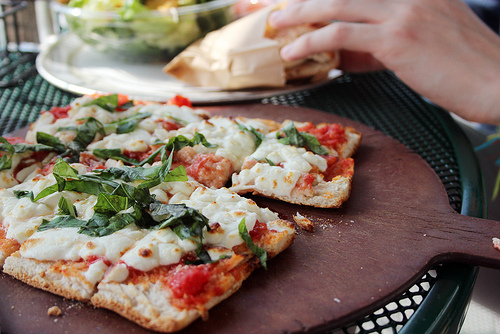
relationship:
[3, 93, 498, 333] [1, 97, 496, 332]
pizza on tray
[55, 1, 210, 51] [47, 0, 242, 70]
salad in bowl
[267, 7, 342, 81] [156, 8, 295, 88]
sandwich in wrapper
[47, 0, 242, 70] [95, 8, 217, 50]
bowl with greens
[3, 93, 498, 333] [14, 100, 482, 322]
pizza served on board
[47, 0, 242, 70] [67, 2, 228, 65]
bowl of salad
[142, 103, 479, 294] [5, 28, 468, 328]
board on table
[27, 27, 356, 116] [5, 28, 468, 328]
plate on table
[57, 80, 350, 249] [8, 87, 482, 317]
square pizza on serving tray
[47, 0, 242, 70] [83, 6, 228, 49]
bowl of salad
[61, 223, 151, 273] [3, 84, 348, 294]
cheese on pizza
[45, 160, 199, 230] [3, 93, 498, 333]
spinach on pizza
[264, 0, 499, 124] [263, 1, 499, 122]
hand on person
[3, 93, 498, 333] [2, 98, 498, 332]
pizza on board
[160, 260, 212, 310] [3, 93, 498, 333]
tomato on pizza